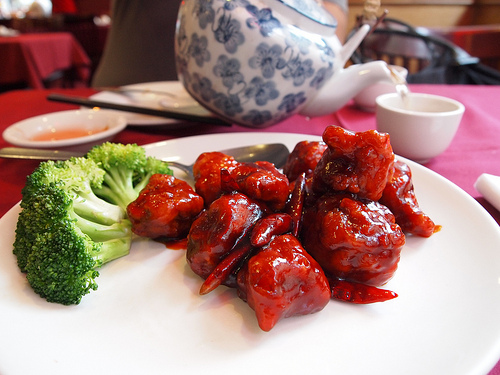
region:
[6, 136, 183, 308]
pieces of green broccoli on white plate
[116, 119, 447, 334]
meat covered in red sauce on white plate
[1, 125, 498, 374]
circular white plate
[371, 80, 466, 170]
round white tea cup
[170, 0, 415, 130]
white and blue ceramic tea pot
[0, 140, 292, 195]
silver spoon lying on white plate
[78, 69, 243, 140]
small white plate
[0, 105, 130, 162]
small white bowl with liquid in it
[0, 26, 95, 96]
restaurant table with red tablecloth on it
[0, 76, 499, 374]
restaurant table with red tablecloth on it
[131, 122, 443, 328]
Orange chicken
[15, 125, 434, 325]
Orange chicken and broccoli on plate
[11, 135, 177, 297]
Two green broccoli trees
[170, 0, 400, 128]
blue and white teapot pouring tea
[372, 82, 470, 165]
White tea cup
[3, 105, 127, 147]
White sauce dish with yellow sauce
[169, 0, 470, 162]
Teapot pouring tea into teacup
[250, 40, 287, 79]
Blue floral design on teapot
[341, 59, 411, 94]
Spout of teapot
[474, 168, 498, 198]
Edge of white napkin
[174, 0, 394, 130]
a blue and white tea pot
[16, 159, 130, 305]
a green broccoli head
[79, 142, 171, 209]
a green broccoli head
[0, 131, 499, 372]
a white plate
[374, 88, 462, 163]
a white tea cup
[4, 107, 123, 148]
a small white bowl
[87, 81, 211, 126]
a white plate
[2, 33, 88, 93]
a red tablecloth in distance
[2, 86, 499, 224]
a red tablecloth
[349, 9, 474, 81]
a wooden chair in distance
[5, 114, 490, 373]
food on a plate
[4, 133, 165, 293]
three brocolli florets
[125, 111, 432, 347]
chicken wings covered in sauce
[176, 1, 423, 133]
blue and white tea kettle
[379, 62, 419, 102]
liquid coming out of the spout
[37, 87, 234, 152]
chopsticks on the edge of the plate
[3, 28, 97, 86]
dark red tablecloth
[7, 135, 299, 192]
spoon laying on the plate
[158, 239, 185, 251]
sauce smeared on the plate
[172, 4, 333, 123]
blue flowers on the pot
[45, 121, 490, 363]
A white plate with food on it.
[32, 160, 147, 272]
Broccoli on a white plate.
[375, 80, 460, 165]
A white teacup.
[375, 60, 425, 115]
liquid being poured into a white cup.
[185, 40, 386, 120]
A teapot with blue floral designs.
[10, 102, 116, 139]
A small dish with a yellow substance in it.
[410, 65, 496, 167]
A pink tablecloth on the table.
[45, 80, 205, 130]
Chopsticks sitting on a white plate.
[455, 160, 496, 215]
A white napkin sitting next to a plate.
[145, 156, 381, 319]
Red colored food on a white plate.